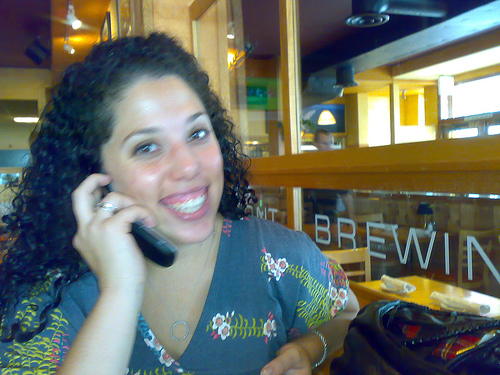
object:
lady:
[0, 15, 362, 375]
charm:
[168, 316, 194, 342]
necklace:
[148, 229, 215, 342]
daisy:
[261, 336, 271, 345]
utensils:
[444, 299, 485, 313]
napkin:
[430, 290, 492, 317]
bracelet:
[301, 329, 331, 365]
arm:
[59, 286, 146, 375]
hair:
[0, 32, 259, 342]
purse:
[428, 325, 500, 364]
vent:
[347, 11, 392, 27]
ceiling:
[0, 3, 500, 82]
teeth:
[166, 195, 212, 214]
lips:
[161, 191, 217, 223]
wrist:
[89, 290, 153, 326]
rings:
[96, 198, 117, 216]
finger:
[70, 173, 112, 224]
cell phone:
[128, 222, 181, 269]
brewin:
[304, 213, 451, 270]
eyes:
[183, 126, 222, 148]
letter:
[391, 222, 442, 271]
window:
[447, 71, 500, 118]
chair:
[322, 247, 372, 283]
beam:
[344, 1, 500, 74]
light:
[72, 17, 86, 30]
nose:
[168, 139, 201, 183]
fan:
[365, 3, 451, 18]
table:
[350, 274, 500, 321]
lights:
[61, 41, 77, 57]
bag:
[328, 294, 500, 374]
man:
[304, 126, 338, 153]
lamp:
[414, 201, 435, 230]